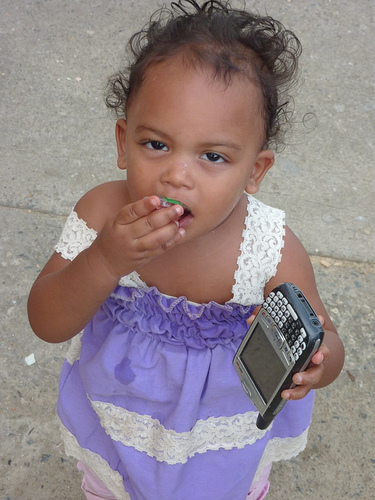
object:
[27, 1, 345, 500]
girl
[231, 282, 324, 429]
phone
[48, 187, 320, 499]
dress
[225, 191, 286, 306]
lace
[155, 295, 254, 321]
ruffles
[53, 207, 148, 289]
strap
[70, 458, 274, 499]
pants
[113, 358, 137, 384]
spot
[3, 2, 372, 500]
sidewalk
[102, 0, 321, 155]
hair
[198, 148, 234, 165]
eye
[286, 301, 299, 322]
button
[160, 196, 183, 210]
candy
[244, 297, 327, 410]
hand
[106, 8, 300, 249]
head